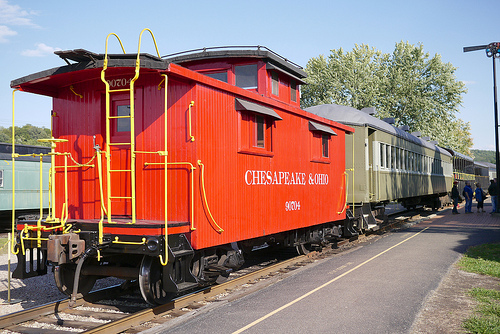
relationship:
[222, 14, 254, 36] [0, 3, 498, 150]
clouds in sky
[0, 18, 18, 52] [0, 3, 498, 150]
cloud in sky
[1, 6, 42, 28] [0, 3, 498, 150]
cloud in sky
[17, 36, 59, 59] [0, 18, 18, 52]
cloud in cloud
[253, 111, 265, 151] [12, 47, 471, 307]
window on train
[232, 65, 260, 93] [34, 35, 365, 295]
window on train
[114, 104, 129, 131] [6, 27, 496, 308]
window on train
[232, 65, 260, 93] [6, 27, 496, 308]
window on train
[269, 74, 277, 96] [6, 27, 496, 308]
window on train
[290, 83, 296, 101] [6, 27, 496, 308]
window on train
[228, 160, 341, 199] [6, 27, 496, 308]
name on train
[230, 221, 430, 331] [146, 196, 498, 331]
line on road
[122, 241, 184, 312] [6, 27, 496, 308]
wheel on train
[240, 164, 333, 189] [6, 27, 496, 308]
text on train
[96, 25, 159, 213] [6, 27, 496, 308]
ladder on train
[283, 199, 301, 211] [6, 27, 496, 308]
number on train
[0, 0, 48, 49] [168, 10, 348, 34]
white clouds in sky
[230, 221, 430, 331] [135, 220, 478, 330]
line on pavement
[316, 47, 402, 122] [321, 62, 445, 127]
leaves on trees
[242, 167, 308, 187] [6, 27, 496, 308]
written on train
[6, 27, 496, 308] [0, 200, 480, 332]
train on tracks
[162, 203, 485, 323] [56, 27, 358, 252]
road near train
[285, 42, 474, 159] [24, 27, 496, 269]
tree beyond train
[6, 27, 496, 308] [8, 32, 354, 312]
train with a caboose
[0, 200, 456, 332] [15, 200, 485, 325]
train tracks on ground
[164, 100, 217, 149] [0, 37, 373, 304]
handle on caboose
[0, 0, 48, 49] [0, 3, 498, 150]
white clouds in sky